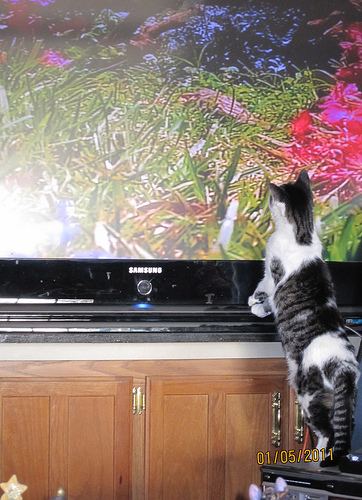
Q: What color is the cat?
A: Black and white.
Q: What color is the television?
A: Black.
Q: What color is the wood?
A: Brown.